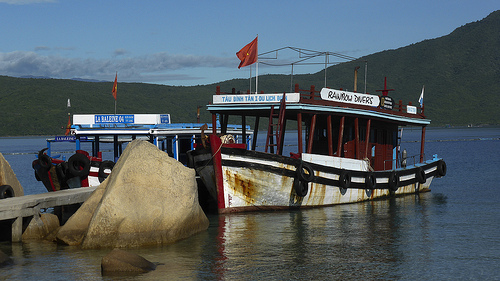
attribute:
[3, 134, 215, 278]
rocks — large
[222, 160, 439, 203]
stains — rust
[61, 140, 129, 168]
area — seating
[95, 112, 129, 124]
writing — vietnamese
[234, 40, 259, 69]
flag — red, small, vietnamese, high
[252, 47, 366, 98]
frame — tarp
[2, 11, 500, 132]
terrain — jungle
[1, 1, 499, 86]
sky — cloudy, blue, dark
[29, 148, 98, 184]
tires — rubber, tied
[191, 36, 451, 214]
boat — present, vietnamese, small, docked, surrounded, red white, blue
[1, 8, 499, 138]
mountains — existing, green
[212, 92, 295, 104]
sign — vietnamese, blue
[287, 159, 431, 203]
life preservers — black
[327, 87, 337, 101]
letter — black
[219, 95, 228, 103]
letter — blue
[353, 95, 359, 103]
letter — black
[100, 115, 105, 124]
letter — white